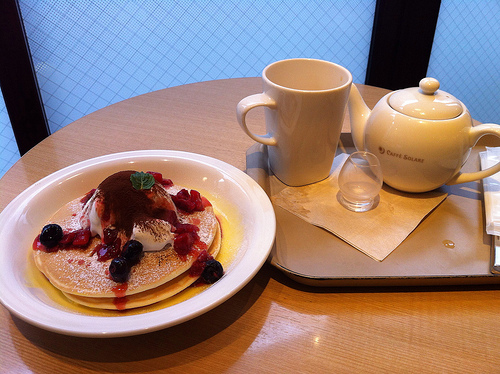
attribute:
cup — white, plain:
[237, 58, 352, 186]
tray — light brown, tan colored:
[246, 133, 499, 287]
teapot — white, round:
[349, 77, 499, 194]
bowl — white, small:
[1, 150, 276, 339]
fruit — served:
[109, 258, 129, 283]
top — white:
[387, 77, 462, 120]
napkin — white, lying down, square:
[271, 152, 449, 261]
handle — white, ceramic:
[237, 92, 276, 146]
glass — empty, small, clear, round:
[337, 151, 384, 212]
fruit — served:
[122, 241, 143, 262]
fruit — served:
[40, 224, 62, 247]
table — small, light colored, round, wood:
[1, 76, 499, 373]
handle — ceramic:
[446, 124, 499, 184]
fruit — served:
[203, 260, 223, 282]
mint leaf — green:
[130, 171, 155, 190]